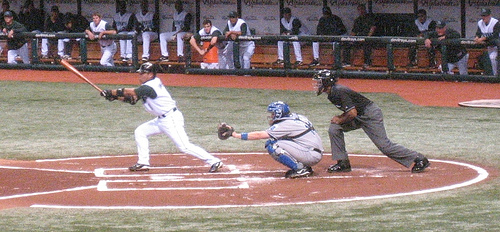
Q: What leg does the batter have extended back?
A: Left.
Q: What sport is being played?
A: Baseball.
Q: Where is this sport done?
A: Stadium.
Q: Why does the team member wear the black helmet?
A: Safety.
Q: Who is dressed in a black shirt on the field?
A: An umpire.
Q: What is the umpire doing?
A: Watching players.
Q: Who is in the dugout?
A: Baseball players.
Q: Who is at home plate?
A: A batter.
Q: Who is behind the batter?
A: A catcher.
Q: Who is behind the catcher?
A: An umpire.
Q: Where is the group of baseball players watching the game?
A: In the dugout.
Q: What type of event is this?
A: A baseball game.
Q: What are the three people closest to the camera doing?
A: Playing baseball.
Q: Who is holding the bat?
A: A baseball player.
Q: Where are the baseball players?
A: On the field.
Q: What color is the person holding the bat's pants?
A: White.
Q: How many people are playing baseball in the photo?
A: Three.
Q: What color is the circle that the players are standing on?
A: Brown.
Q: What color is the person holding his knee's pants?
A: Gray.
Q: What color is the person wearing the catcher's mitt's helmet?
A: Blue.